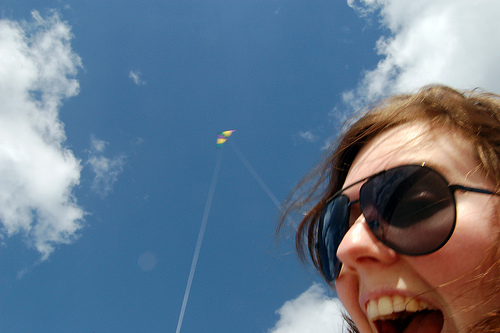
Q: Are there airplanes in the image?
A: No, there are no airplanes.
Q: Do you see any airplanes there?
A: No, there are no airplanes.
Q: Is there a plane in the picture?
A: No, there are no airplanes.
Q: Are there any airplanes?
A: No, there are no airplanes.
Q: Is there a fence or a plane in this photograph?
A: No, there are no airplanes or fences.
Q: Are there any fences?
A: No, there are no fences.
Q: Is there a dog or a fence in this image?
A: No, there are no fences or dogs.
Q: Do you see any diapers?
A: No, there are no diapers.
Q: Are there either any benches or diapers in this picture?
A: No, there are no diapers or benches.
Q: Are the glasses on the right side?
A: Yes, the glasses are on the right of the image.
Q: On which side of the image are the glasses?
A: The glasses are on the right of the image.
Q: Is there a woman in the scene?
A: Yes, there is a woman.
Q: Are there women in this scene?
A: Yes, there is a woman.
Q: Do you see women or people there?
A: Yes, there is a woman.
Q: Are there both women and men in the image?
A: No, there is a woman but no men.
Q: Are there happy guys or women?
A: Yes, there is a happy woman.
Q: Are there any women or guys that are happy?
A: Yes, the woman is happy.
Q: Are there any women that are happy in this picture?
A: Yes, there is a happy woman.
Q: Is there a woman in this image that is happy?
A: Yes, there is a woman that is happy.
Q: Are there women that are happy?
A: Yes, there is a woman that is happy.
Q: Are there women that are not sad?
A: Yes, there is a happy woman.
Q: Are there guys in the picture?
A: No, there are no guys.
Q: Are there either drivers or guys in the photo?
A: No, there are no guys or drivers.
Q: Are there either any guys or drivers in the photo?
A: No, there are no guys or drivers.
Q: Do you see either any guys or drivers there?
A: No, there are no guys or drivers.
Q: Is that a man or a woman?
A: That is a woman.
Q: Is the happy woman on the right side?
A: Yes, the woman is on the right of the image.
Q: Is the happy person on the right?
A: Yes, the woman is on the right of the image.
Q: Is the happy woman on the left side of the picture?
A: No, the woman is on the right of the image.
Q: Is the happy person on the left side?
A: No, the woman is on the right of the image.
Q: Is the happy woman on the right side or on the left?
A: The woman is on the right of the image.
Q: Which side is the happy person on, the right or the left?
A: The woman is on the right of the image.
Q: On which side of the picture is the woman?
A: The woman is on the right of the image.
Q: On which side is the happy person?
A: The woman is on the right of the image.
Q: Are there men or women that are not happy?
A: No, there is a woman but she is happy.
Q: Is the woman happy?
A: Yes, the woman is happy.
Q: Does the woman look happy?
A: Yes, the woman is happy.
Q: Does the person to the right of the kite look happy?
A: Yes, the woman is happy.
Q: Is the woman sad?
A: No, the woman is happy.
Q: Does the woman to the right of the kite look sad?
A: No, the woman is happy.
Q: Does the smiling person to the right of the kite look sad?
A: No, the woman is happy.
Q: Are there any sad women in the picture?
A: No, there is a woman but she is happy.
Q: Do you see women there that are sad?
A: No, there is a woman but she is happy.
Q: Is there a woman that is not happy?
A: No, there is a woman but she is happy.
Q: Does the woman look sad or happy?
A: The woman is happy.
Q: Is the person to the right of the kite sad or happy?
A: The woman is happy.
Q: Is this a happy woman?
A: Yes, this is a happy woman.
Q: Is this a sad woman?
A: No, this is a happy woman.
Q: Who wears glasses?
A: The woman wears glasses.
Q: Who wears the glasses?
A: The woman wears glasses.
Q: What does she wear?
A: The woman wears glasses.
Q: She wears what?
A: The woman wears glasses.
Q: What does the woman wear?
A: The woman wears glasses.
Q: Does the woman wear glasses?
A: Yes, the woman wears glasses.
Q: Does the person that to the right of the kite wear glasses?
A: Yes, the woman wears glasses.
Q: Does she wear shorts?
A: No, the woman wears glasses.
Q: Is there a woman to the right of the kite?
A: Yes, there is a woman to the right of the kite.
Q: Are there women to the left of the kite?
A: No, the woman is to the right of the kite.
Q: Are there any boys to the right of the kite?
A: No, there is a woman to the right of the kite.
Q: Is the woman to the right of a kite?
A: Yes, the woman is to the right of a kite.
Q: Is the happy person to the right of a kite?
A: Yes, the woman is to the right of a kite.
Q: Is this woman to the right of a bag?
A: No, the woman is to the right of a kite.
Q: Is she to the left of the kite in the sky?
A: No, the woman is to the right of the kite.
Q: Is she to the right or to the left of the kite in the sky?
A: The woman is to the right of the kite.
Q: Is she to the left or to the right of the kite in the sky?
A: The woman is to the right of the kite.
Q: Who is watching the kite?
A: The woman is watching the kite.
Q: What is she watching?
A: The woman is watching the kite.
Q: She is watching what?
A: The woman is watching the kite.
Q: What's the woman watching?
A: The woman is watching the kite.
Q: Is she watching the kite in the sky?
A: Yes, the woman is watching the kite.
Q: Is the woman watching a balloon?
A: No, the woman is watching the kite.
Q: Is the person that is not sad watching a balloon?
A: No, the woman is watching the kite.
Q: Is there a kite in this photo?
A: Yes, there is a kite.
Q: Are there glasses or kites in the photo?
A: Yes, there is a kite.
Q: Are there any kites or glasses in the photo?
A: Yes, there is a kite.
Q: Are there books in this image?
A: No, there are no books.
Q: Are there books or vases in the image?
A: No, there are no books or vases.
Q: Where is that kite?
A: The kite is in the sky.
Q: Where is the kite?
A: The kite is in the sky.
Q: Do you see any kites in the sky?
A: Yes, there is a kite in the sky.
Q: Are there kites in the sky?
A: Yes, there is a kite in the sky.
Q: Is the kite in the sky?
A: Yes, the kite is in the sky.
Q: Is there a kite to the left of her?
A: Yes, there is a kite to the left of the woman.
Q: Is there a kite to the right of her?
A: No, the kite is to the left of the woman.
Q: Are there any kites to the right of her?
A: No, the kite is to the left of the woman.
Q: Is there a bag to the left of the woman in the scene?
A: No, there is a kite to the left of the woman.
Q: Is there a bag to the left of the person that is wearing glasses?
A: No, there is a kite to the left of the woman.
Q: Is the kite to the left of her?
A: Yes, the kite is to the left of the woman.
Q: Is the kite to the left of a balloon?
A: No, the kite is to the left of the woman.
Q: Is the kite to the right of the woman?
A: No, the kite is to the left of the woman.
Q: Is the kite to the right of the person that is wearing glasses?
A: No, the kite is to the left of the woman.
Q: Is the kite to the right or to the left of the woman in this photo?
A: The kite is to the left of the woman.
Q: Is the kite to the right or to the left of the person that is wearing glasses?
A: The kite is to the left of the woman.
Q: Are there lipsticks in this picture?
A: No, there are no lipsticks.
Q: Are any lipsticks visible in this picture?
A: No, there are no lipsticks.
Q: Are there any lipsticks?
A: No, there are no lipsticks.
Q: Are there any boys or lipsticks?
A: No, there are no lipsticks or boys.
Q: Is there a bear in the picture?
A: No, there are no bears.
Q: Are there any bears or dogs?
A: No, there are no bears or dogs.